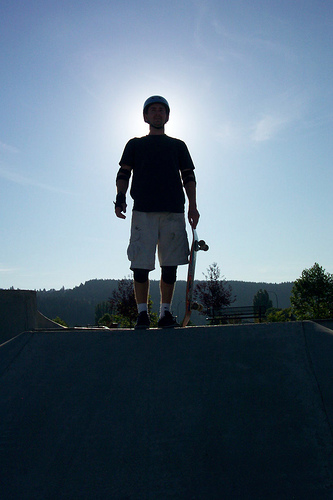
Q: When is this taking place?
A: Daytime.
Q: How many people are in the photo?
A: One.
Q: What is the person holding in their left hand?
A: Skateboard.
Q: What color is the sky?
A: Blue and white.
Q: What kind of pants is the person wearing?
A: Shorts.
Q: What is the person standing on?
A: Raised surface.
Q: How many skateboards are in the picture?
A: One.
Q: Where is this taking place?
A: At a skatepark.